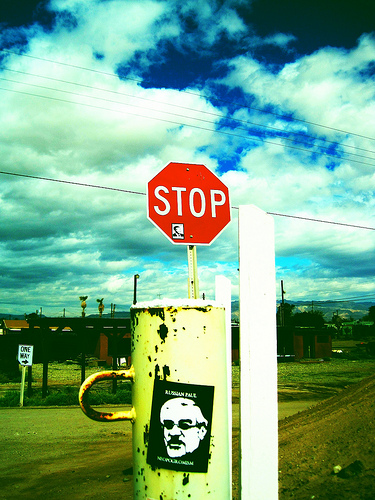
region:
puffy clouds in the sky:
[0, 0, 373, 145]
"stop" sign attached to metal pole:
[145, 143, 236, 297]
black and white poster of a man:
[140, 369, 212, 488]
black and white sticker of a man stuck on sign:
[163, 217, 190, 250]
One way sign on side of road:
[10, 335, 41, 406]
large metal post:
[76, 294, 237, 499]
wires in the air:
[0, 84, 373, 216]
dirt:
[287, 376, 368, 497]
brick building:
[276, 326, 337, 365]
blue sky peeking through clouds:
[144, 10, 333, 165]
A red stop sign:
[148, 161, 232, 244]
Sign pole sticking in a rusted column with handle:
[79, 244, 231, 498]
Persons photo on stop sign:
[172, 223, 185, 241]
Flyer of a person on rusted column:
[144, 379, 214, 475]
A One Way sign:
[16, 342, 34, 365]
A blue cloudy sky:
[0, 0, 373, 103]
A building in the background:
[93, 320, 332, 366]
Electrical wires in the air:
[0, 46, 372, 163]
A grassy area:
[2, 422, 131, 497]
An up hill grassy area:
[279, 380, 374, 457]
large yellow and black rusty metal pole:
[79, 302, 231, 498]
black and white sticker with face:
[146, 376, 211, 471]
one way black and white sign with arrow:
[19, 345, 34, 365]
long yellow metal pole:
[20, 364, 26, 406]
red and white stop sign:
[147, 160, 233, 246]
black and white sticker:
[171, 222, 182, 239]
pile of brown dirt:
[32, 378, 372, 498]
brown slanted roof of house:
[3, 317, 72, 333]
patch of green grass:
[2, 378, 130, 404]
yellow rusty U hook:
[77, 366, 140, 421]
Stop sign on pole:
[137, 155, 237, 248]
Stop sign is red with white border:
[136, 150, 241, 252]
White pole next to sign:
[226, 192, 291, 496]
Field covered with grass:
[4, 339, 371, 496]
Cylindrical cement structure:
[75, 275, 243, 494]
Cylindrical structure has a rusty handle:
[65, 292, 249, 494]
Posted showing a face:
[140, 370, 221, 480]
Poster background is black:
[138, 370, 222, 481]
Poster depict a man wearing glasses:
[135, 371, 221, 480]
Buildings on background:
[4, 312, 369, 363]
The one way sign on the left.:
[15, 344, 32, 407]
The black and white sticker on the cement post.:
[144, 377, 219, 471]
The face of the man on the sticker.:
[160, 395, 209, 457]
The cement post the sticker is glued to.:
[134, 298, 230, 497]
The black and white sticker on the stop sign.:
[170, 222, 186, 241]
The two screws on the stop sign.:
[182, 162, 199, 241]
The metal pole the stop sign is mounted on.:
[187, 244, 198, 296]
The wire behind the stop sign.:
[3, 170, 374, 235]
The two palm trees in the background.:
[74, 289, 110, 317]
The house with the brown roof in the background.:
[1, 316, 73, 332]